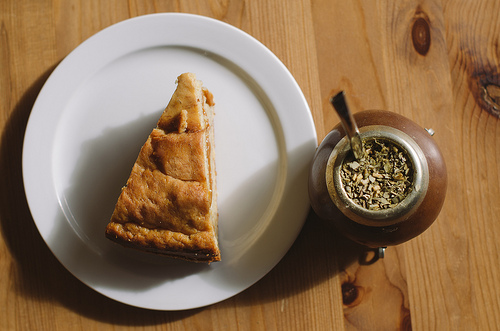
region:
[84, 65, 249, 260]
pie on a plate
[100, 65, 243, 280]
the pie is brown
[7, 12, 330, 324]
the plate is white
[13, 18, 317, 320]
the plate is white with a rim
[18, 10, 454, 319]
the plate is on the table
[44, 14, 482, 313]
the table is made of wood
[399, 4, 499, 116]
the wood has some knots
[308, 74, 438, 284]
brown cup near the plate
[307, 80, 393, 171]
spoon in the cup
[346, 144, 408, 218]
seeds in the cup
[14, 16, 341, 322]
pie on a plate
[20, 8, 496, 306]
the plate is on a table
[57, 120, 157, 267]
shadow of pie on plate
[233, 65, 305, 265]
the white plate has a rim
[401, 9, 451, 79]
knots in the wooden table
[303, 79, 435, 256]
brown cup next to plate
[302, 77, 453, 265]
cup has a spoon in it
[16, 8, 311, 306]
all white plate on table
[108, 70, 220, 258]
brown slice of pie on plate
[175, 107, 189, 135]
crumb of the pie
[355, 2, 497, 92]
table made of wood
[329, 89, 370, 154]
silver spoon in bowl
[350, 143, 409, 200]
grain of oats in bowl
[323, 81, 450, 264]
brown cup bowl on table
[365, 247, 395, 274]
silver handle of bowl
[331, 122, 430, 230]
silver rim of the cup bowl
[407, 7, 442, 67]
brown spot in the wood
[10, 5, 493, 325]
wooden table with dark oval markings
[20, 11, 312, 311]
round white plate with rim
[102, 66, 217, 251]
wedge of pie on top of plate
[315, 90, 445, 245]
brown container with metal rim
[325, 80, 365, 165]
silver utensil inside container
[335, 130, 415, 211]
tan and brown flakes of seasoning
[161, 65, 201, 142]
pointy edge of pie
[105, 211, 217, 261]
raised curved edge of pie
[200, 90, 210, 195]
thin light-brown pie filling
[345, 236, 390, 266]
metal foot and its shadow at bottom of container